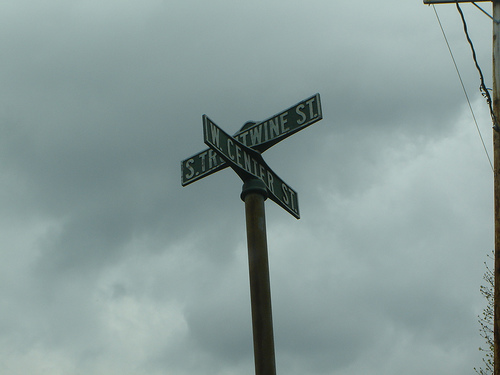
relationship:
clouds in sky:
[1, 3, 486, 368] [1, 0, 497, 373]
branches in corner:
[472, 218, 495, 373] [469, 248, 497, 373]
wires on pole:
[436, 18, 488, 101] [466, 1, 498, 373]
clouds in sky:
[0, 0, 494, 375] [8, 9, 178, 371]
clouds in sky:
[0, 0, 494, 375] [316, 9, 484, 373]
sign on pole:
[181, 93, 324, 188] [241, 192, 279, 369]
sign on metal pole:
[202, 113, 301, 220] [239, 120, 276, 375]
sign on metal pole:
[167, 78, 312, 188] [239, 120, 276, 375]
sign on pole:
[181, 93, 324, 188] [219, 200, 306, 344]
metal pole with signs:
[239, 120, 276, 375] [170, 89, 325, 217]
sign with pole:
[181, 93, 324, 188] [246, 193, 279, 373]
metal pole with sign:
[239, 120, 276, 375] [181, 93, 324, 188]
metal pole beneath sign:
[238, 192, 273, 374] [162, 90, 328, 217]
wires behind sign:
[432, 2, 500, 172] [177, 89, 324, 222]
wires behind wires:
[432, 2, 500, 172] [432, 2, 500, 172]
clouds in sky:
[0, 0, 494, 375] [4, 21, 498, 224]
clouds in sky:
[0, 0, 494, 375] [12, 60, 167, 318]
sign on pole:
[181, 93, 324, 188] [238, 177, 274, 374]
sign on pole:
[201, 113, 298, 218] [238, 177, 274, 374]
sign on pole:
[181, 93, 324, 188] [235, 194, 320, 366]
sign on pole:
[181, 93, 324, 188] [238, 169, 288, 372]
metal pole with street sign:
[239, 120, 276, 375] [178, 89, 323, 189]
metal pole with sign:
[239, 120, 276, 375] [202, 113, 301, 220]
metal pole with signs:
[239, 120, 276, 375] [107, 50, 342, 370]